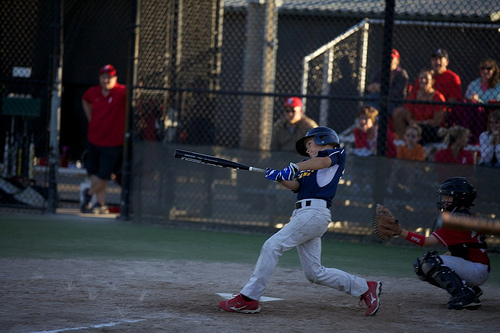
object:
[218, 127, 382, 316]
batter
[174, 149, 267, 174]
bat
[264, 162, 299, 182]
baseball gloves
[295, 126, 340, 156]
helmet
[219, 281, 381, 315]
red shoes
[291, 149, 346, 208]
shirt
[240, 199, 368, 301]
pants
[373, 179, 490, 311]
catcher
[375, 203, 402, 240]
baseball mitt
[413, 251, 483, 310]
protective gear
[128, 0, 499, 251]
chain link fence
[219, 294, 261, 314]
home plate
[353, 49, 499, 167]
spectators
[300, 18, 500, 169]
stands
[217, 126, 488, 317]
kids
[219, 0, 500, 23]
covers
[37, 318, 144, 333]
baseline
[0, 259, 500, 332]
dirt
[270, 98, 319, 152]
spectator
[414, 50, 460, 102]
spectator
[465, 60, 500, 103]
spectator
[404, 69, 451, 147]
person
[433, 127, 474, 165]
person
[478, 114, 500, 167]
person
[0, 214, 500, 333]
field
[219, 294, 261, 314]
shoe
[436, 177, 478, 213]
helmet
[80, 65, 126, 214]
man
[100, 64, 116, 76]
cap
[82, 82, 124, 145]
red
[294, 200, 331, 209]
black belt